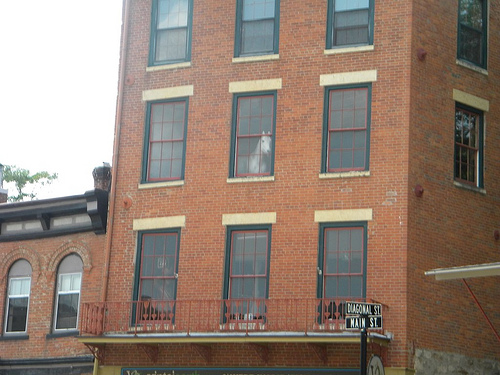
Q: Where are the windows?
A: On building.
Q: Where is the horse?
A: In window.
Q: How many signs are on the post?
A: Two.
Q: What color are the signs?
A: Black.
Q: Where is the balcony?
A: On building.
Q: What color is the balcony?
A: Red.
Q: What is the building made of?
A: Brick.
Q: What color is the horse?
A: White.